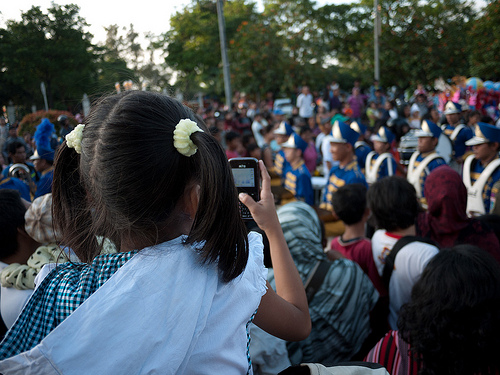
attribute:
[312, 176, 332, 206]
drum — white, topped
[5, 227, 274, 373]
fabric — white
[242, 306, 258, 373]
end — frilly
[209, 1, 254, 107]
pole — tall, blue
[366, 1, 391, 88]
pole — tall, blue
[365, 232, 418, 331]
bag — red, black, white, striped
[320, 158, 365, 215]
shirt — blue, gold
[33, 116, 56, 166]
feather — blue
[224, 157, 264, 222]
phone — black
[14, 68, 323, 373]
girl — Little 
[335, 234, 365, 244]
collar — brown, green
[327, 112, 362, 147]
hat — blue, white, military hat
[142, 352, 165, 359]
fabric — white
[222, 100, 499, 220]
band — marching band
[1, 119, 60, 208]
band — marching band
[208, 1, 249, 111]
pole — metal, above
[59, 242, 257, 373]
fabric — white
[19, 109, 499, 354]
people — watching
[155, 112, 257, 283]
holder hair — yellow, ponytail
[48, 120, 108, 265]
holder hair — ponytail, yellow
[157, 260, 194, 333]
hood — white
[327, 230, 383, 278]
shirt — red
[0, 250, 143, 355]
fabric — blue plaid, green 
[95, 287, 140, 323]
fabric — white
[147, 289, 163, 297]
fabric — white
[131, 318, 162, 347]
fabric — white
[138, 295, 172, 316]
fabric — white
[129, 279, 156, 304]
fabric — white